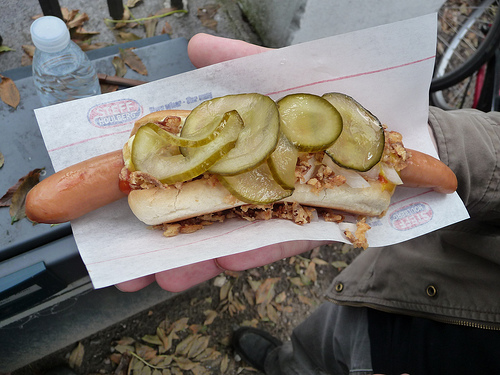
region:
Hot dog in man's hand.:
[39, 67, 454, 295]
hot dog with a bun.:
[20, 73, 440, 298]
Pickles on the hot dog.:
[101, 79, 446, 279]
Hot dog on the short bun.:
[43, 59, 428, 281]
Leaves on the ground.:
[198, 257, 280, 339]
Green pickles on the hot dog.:
[201, 81, 389, 238]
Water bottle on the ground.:
[16, 17, 133, 163]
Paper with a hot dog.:
[26, 57, 476, 316]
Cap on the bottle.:
[23, 10, 84, 62]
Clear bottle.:
[12, 18, 137, 130]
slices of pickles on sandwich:
[125, 95, 413, 207]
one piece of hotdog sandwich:
[24, 88, 490, 288]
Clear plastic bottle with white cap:
[27, 14, 102, 106]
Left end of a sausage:
[20, 150, 127, 240]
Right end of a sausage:
[398, 143, 460, 197]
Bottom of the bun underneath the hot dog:
[117, 173, 392, 222]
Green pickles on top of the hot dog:
[117, 88, 399, 210]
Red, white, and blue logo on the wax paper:
[87, 98, 147, 130]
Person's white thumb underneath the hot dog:
[182, 25, 280, 72]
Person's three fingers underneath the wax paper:
[108, 244, 330, 306]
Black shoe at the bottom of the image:
[226, 321, 286, 368]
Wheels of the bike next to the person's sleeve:
[431, 0, 498, 112]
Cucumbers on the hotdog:
[121, 92, 382, 199]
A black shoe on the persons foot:
[230, 323, 282, 363]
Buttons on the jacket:
[333, 280, 443, 297]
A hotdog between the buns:
[25, 140, 456, 230]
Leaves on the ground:
[70, 264, 322, 373]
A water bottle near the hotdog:
[26, 20, 105, 101]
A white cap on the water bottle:
[28, 13, 71, 49]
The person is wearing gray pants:
[266, 295, 371, 373]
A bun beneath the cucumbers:
[134, 173, 389, 228]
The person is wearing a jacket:
[325, 99, 499, 329]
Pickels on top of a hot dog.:
[71, 99, 458, 262]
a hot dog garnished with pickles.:
[48, 149, 456, 236]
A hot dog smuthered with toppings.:
[73, 143, 469, 227]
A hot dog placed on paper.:
[48, 110, 479, 248]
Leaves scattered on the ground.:
[167, 314, 243, 370]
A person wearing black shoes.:
[220, 310, 298, 372]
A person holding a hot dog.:
[21, 105, 455, 313]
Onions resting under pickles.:
[316, 153, 401, 218]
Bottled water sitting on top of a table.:
[8, 22, 86, 158]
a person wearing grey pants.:
[284, 306, 364, 372]